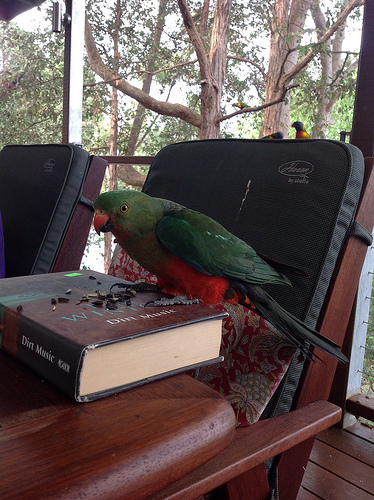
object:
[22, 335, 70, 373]
writing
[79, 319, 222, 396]
pages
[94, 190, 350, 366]
bird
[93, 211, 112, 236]
beak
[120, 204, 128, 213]
eye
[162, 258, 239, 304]
bottom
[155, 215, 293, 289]
wing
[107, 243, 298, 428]
cushion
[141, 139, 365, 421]
cushion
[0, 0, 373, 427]
background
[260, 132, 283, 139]
birds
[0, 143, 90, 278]
cushion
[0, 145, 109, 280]
chair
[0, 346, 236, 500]
table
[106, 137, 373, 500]
chair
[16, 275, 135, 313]
food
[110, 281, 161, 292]
claws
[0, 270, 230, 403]
book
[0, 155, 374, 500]
wood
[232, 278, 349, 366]
feathers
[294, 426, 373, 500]
floor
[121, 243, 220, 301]
underneath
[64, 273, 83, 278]
sticker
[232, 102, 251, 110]
bird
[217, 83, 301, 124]
branch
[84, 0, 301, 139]
tree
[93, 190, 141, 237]
head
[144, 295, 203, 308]
leg